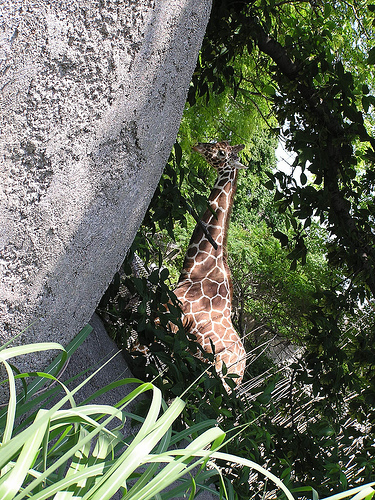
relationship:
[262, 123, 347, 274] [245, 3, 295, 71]
leaves on branch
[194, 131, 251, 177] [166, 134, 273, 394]
head of giraffe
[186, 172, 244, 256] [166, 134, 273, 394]
neck of giraffe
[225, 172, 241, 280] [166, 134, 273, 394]
mane on giraffe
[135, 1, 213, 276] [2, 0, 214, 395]
shadow on cement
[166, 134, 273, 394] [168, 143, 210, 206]
giraffe grazing on tree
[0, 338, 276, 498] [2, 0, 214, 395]
grass in front of stone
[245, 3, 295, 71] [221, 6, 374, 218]
branch on tree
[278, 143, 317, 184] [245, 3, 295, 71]
sky by branch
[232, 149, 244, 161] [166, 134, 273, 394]
horn on giraffe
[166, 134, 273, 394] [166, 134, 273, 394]
giraffe of giraffe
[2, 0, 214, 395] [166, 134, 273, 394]
rock next to giraffe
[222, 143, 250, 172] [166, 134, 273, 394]
ears of giraffe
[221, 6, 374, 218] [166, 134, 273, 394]
trees by giraffe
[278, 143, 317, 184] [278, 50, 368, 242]
sky by trees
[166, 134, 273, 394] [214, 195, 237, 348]
giraffe back light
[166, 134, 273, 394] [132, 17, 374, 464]
giraffe in wild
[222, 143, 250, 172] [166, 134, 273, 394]
ears on giraffe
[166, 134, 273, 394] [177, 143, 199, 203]
giraffe looking for food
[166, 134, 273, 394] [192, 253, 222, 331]
giraffe has spots